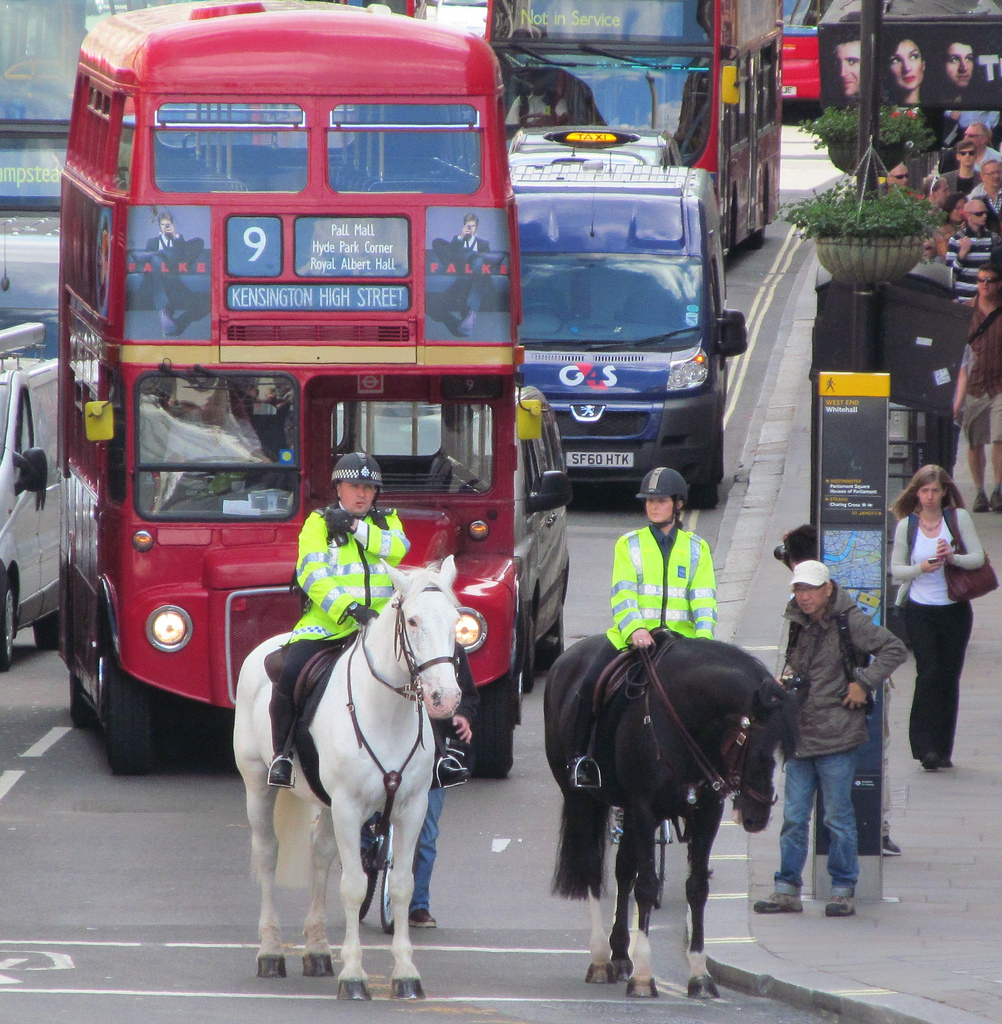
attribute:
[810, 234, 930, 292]
basket — hanging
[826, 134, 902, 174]
basket — hanging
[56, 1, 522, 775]
bus — red, double decker, large red commuter, Red double decker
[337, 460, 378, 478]
department — British police 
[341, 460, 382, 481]
department — British police 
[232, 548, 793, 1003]
horse — Beautiful healthy, Beautiful healthy white 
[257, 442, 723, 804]
police — British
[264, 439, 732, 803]
officers — British police 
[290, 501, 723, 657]
vests — bright colored , reflective 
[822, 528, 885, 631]
maps — corners 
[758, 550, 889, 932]
visitors — tourists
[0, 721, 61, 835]
lines — white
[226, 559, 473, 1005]
horse — white, white police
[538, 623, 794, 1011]
horse — Black police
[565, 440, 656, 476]
plate — License 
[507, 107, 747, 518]
car — blue 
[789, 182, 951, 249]
plant — Green  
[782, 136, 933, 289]
pot — hanging 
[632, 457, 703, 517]
helmet — black   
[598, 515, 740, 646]
coat — bright green  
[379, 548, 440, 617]
mane — white 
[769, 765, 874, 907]
jeans — blue 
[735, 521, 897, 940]
corner — street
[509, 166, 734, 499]
van — blue